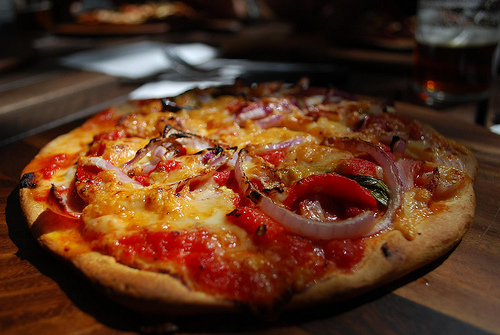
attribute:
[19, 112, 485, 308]
pizza — part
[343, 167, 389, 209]
leaf — green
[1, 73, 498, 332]
table — part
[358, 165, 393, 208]
leaf — green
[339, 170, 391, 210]
leaf — green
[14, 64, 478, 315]
pizza — round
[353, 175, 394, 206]
vegetable — green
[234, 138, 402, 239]
onion — part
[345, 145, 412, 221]
leaf — green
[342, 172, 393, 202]
leaf — green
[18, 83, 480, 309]
pizza — small, round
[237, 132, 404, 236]
onion — big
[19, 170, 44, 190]
spot — dark, big, black